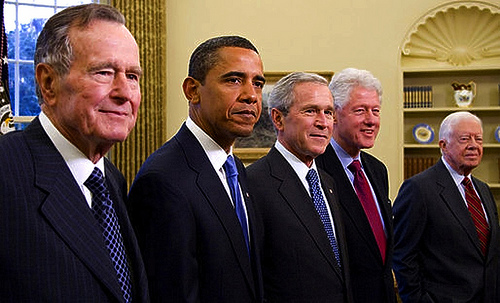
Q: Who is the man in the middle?
A: George W. Bush.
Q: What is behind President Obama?
A: A window.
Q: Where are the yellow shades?
A: Pulled open to the right of the window.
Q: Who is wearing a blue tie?
A: The three men on the left.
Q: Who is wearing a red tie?
A: The two men on the right.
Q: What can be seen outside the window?
A: A tree.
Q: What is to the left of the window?
A: A flag.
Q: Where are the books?
A: On the shelves.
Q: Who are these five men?
A: Presidents.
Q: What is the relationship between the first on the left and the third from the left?
A: Father and son.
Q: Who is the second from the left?
A: President Obama.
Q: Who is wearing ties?
A: The men.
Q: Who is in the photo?
A: The presidents.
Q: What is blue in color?
A: The tie on Obama.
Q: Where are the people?
A: In a room.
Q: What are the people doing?
A: Looking at the same thing.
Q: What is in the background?
A: A window.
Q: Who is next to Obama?
A: George Bush.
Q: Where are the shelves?
A: Next to the people.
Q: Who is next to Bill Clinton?
A: Jimmy Carter.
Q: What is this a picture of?
A: Presidents.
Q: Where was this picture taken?
A: The white house.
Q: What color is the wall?
A: Beige.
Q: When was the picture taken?
A: During the day.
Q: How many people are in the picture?
A: 5.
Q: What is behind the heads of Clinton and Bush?
A: A painting.